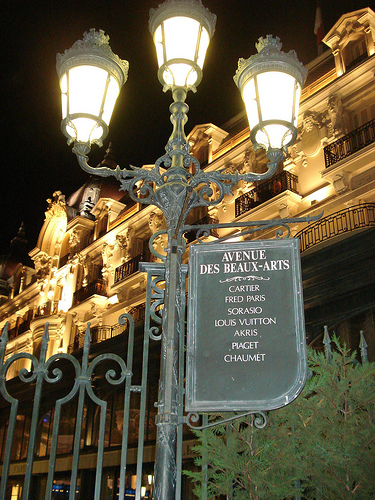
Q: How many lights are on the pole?
A: Three.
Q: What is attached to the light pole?
A: A sign.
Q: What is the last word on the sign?
A: Chaumet.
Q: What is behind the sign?
A: A bush.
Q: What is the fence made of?
A: Metal.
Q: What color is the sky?
A: Black.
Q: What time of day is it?
A: At night.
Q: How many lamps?
A: Three lamps.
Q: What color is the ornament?
A: Green.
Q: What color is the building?
A: White.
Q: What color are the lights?
A: Yellow.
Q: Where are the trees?
A: Below the lampost.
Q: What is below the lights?
A: The sign.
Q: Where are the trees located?
A: To the right of the lamp post.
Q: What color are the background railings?
A: Black.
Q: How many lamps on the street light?
A: 3.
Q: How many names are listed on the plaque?
A: 7.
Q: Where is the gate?
A: In front of the building.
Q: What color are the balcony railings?
A: Black.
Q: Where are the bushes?
A: On the right.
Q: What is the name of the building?
A: Avenue Des Beaux-Arts.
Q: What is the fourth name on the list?
A: Louis Vuitton.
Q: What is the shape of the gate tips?
A: Arrows.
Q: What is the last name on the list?
A: Chaumet.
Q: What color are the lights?
A: Yellow.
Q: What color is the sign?
A: Green.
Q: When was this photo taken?
A: At night.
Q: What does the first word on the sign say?
A: AVENUE.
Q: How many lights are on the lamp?
A: 3.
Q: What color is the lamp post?
A: Black.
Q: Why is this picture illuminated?
A: Because there is a lamp.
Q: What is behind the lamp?
A: A building.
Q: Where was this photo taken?
A: On the street.